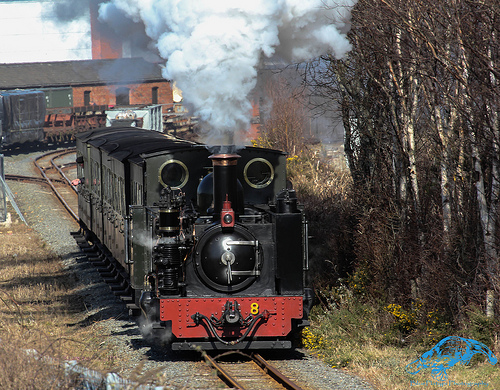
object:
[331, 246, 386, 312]
flowers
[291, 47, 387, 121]
branches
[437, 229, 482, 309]
branches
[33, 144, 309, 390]
railway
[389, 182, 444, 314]
branches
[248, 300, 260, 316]
number eight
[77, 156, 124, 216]
windows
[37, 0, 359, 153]
smoke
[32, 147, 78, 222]
tracks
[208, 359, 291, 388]
tracks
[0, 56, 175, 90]
roof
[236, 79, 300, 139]
wall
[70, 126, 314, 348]
black train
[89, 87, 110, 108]
wall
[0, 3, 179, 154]
building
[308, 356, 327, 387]
rocks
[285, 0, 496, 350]
tree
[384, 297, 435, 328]
flowers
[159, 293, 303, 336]
red bumper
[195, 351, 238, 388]
metal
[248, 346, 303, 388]
metal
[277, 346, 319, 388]
road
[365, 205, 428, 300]
plant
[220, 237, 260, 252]
metal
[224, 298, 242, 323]
metal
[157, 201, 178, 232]
metal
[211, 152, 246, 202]
metal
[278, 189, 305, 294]
metal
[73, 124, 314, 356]
engine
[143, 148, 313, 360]
front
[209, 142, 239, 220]
chimney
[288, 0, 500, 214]
brown branches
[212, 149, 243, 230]
smoke stack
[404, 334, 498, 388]
blue object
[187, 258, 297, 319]
bad sentence